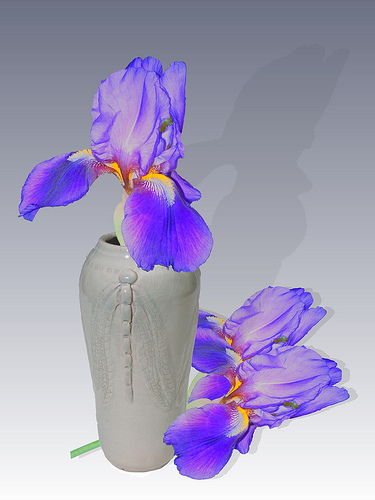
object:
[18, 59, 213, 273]
flower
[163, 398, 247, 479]
petals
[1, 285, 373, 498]
ground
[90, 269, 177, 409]
design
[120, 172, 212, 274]
petal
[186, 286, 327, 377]
flower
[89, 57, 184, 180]
petal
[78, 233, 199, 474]
vase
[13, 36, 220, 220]
iris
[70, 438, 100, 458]
stem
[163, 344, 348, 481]
flower